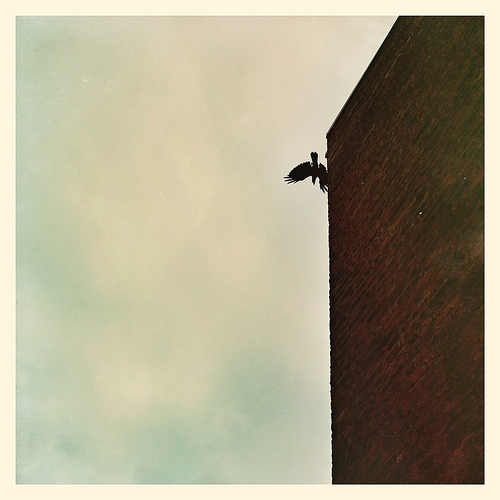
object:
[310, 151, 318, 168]
tail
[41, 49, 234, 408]
clouds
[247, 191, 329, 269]
sillhouette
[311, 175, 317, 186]
head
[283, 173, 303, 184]
feathers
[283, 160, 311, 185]
wing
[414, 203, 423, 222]
spot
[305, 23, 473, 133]
rooftop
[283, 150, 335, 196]
bird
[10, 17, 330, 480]
sky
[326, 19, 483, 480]
building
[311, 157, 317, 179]
underside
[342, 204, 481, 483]
brick